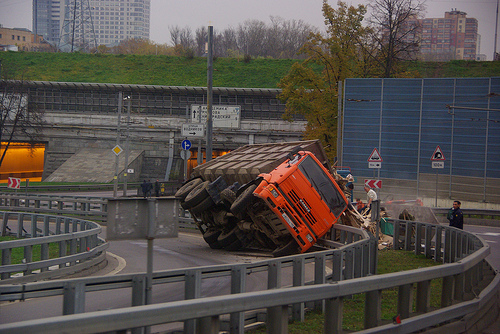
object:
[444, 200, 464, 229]
person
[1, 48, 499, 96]
grass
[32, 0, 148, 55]
building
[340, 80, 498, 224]
fence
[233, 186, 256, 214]
wheel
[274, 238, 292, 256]
wheel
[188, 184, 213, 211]
wheel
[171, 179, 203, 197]
wheel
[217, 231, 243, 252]
wheel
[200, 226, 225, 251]
wheel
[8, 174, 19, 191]
sign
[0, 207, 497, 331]
railing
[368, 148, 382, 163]
sign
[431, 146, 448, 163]
sign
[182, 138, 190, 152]
sign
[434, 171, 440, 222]
post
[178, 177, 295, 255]
tires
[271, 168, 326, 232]
orange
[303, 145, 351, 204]
orange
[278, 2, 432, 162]
tree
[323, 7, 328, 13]
leaf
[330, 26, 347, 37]
leaf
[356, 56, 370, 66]
leaf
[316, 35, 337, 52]
leaf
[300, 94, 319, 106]
leaf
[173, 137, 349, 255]
truck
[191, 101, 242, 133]
sign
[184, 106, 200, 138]
arrows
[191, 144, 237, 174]
lights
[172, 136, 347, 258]
lorry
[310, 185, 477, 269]
goods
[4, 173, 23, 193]
arrow board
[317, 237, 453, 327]
grass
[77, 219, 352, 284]
guard rails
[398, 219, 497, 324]
guard rails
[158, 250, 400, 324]
rails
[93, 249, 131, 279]
lines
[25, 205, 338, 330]
road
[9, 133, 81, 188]
tunnel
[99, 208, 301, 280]
road way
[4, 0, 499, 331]
photo